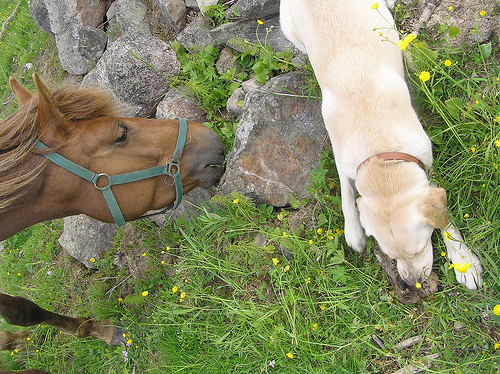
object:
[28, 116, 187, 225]
harness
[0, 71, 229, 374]
horse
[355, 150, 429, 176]
collar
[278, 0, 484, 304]
dog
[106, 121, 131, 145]
eye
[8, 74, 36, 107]
ears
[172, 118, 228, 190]
snout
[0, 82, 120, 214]
mane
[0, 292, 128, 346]
legs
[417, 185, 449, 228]
ears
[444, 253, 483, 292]
paws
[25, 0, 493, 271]
rocks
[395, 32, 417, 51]
flowers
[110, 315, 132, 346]
hooves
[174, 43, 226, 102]
grass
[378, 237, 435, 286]
face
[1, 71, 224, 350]
animals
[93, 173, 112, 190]
circle